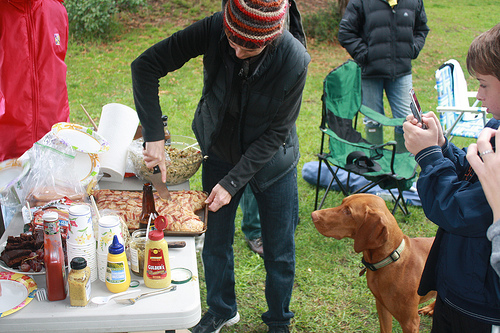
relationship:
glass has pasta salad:
[129, 129, 205, 182] [131, 133, 200, 181]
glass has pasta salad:
[129, 129, 205, 182] [128, 133, 190, 180]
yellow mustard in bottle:
[106, 250, 132, 292] [101, 232, 134, 297]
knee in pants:
[362, 117, 386, 137] [355, 70, 419, 185]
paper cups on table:
[95, 214, 114, 291] [134, 292, 201, 329]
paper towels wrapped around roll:
[96, 102, 139, 182] [93, 100, 143, 181]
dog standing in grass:
[306, 187, 442, 332] [63, 1, 483, 329]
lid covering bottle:
[107, 233, 123, 255] [103, 235, 133, 292]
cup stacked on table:
[65, 205, 97, 283] [0, 171, 200, 329]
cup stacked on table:
[94, 210, 126, 256] [0, 171, 200, 329]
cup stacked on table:
[64, 243, 94, 247] [0, 171, 200, 329]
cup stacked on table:
[97, 216, 125, 284] [0, 171, 200, 329]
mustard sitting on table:
[104, 233, 129, 293] [0, 171, 200, 329]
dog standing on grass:
[306, 187, 442, 332] [433, 7, 460, 38]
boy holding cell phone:
[403, 23, 499, 332] [402, 86, 425, 127]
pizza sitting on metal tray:
[99, 190, 203, 229] [98, 187, 209, 237]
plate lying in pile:
[3, 155, 32, 193] [1, 121, 109, 205]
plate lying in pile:
[0, 171, 199, 332] [1, 121, 109, 205]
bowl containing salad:
[126, 131, 206, 185] [131, 142, 201, 184]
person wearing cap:
[111, 2, 332, 331] [219, 1, 289, 50]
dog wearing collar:
[309, 193, 435, 332] [364, 234, 413, 269]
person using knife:
[131, 0, 311, 333] [135, 147, 190, 206]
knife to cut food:
[135, 147, 190, 206] [129, 167, 248, 246]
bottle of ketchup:
[42, 212, 72, 304] [41, 210, 66, 300]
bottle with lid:
[42, 212, 72, 304] [42, 211, 59, 219]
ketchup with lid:
[41, 210, 66, 300] [42, 211, 59, 219]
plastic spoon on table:
[87, 290, 116, 305] [24, 299, 208, 331]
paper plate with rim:
[0, 269, 37, 320] [3, 268, 40, 318]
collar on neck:
[352, 233, 411, 277] [361, 226, 409, 271]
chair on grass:
[321, 59, 423, 207] [304, 242, 348, 332]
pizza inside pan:
[95, 189, 206, 232] [67, 165, 227, 250]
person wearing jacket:
[0, 0, 67, 159] [0, 2, 70, 159]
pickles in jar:
[129, 243, 149, 268] [126, 227, 151, 274]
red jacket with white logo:
[0, 0, 72, 157] [47, 27, 66, 46]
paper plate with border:
[0, 269, 37, 317] [7, 262, 38, 286]